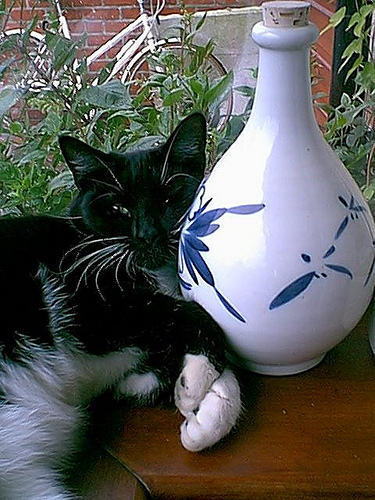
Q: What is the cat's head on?
A: Vase.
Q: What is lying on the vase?
A: Cat.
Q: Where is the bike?
A: Background.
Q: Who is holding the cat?
A: Nobody.